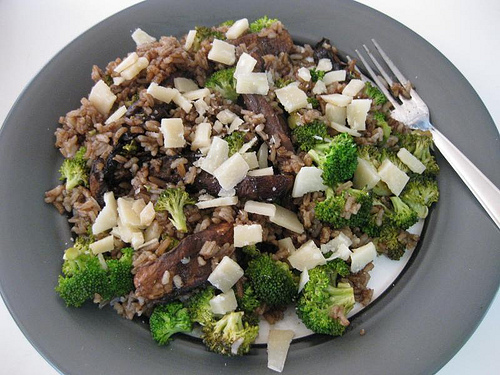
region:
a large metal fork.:
[343, 37, 498, 259]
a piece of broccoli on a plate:
[47, 232, 144, 327]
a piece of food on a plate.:
[231, 218, 270, 255]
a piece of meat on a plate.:
[111, 236, 203, 306]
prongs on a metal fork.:
[348, 35, 416, 110]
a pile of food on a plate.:
[39, 19, 431, 374]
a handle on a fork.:
[424, 121, 498, 245]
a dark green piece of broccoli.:
[43, 241, 143, 312]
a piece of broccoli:
[156, 189, 188, 229]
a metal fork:
[346, 41, 498, 228]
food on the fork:
[393, 78, 412, 101]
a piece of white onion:
[264, 325, 292, 372]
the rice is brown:
[46, 183, 97, 230]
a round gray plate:
[4, 2, 494, 365]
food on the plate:
[46, 15, 443, 362]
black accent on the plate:
[351, 212, 431, 317]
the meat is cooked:
[131, 225, 232, 300]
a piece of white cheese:
[160, 117, 184, 148]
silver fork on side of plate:
[341, 38, 498, 238]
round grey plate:
[0, 3, 491, 373]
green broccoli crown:
[235, 252, 297, 314]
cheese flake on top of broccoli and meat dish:
[199, 253, 247, 295]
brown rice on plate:
[140, 42, 195, 76]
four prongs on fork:
[335, 33, 419, 120]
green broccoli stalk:
[334, 281, 361, 315]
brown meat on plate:
[125, 227, 255, 308]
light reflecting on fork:
[391, 90, 431, 130]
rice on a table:
[55, 76, 215, 208]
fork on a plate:
[336, 28, 486, 177]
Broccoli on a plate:
[303, 127, 446, 267]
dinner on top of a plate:
[45, 33, 457, 358]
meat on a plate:
[131, 225, 258, 309]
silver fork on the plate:
[346, 23, 498, 239]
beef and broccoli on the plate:
[236, 91, 381, 233]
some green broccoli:
[36, 82, 413, 332]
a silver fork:
[327, 29, 498, 231]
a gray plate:
[5, 3, 495, 373]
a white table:
[1, 1, 493, 371]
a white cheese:
[203, 149, 290, 214]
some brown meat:
[42, 25, 479, 359]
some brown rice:
[27, 12, 451, 372]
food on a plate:
[4, 3, 497, 373]